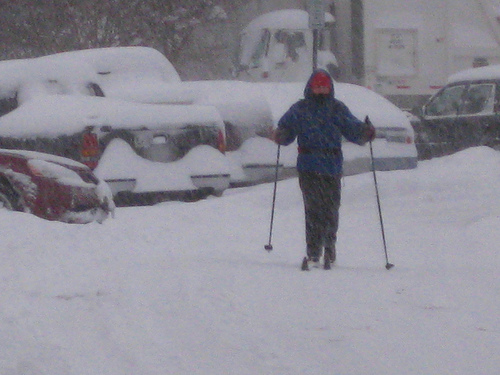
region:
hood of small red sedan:
[1, 145, 121, 226]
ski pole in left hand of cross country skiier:
[360, 111, 402, 274]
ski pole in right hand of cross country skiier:
[262, 118, 283, 257]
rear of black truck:
[3, 59, 233, 211]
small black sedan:
[408, 65, 498, 150]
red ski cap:
[307, 69, 337, 91]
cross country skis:
[294, 247, 339, 274]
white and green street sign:
[305, 1, 327, 75]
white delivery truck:
[237, 0, 499, 104]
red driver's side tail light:
[75, 128, 102, 170]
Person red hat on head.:
[306, 63, 333, 90]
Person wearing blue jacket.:
[295, 110, 347, 155]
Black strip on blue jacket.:
[292, 138, 348, 158]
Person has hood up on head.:
[296, 60, 339, 101]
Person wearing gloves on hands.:
[259, 110, 401, 141]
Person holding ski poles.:
[247, 102, 392, 169]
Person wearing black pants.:
[294, 189, 352, 242]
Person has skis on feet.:
[296, 243, 358, 270]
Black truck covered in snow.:
[102, 118, 202, 149]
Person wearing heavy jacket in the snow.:
[265, 61, 393, 278]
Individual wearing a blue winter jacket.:
[259, 67, 399, 274]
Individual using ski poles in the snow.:
[261, 68, 396, 273]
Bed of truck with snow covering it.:
[76, 104, 231, 205]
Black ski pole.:
[366, 124, 394, 277]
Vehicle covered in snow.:
[409, 67, 498, 155]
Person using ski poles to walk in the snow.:
[264, 60, 392, 274]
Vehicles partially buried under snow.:
[4, 49, 236, 224]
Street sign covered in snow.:
[309, 4, 328, 29]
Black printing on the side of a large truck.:
[381, 34, 408, 54]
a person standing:
[266, 73, 393, 285]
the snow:
[150, 301, 232, 374]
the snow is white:
[128, 274, 208, 344]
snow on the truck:
[103, 147, 195, 182]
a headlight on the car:
[29, 158, 82, 183]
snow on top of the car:
[455, 67, 495, 84]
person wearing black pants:
[300, 176, 336, 253]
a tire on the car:
[3, 185, 25, 214]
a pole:
[360, 139, 402, 276]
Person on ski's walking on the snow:
[259, 68, 394, 275]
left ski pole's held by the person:
[260, 129, 285, 257]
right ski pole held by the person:
[363, 116, 393, 271]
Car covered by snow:
[0, 66, 231, 198]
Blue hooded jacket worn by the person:
[277, 69, 368, 176]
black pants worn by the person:
[296, 169, 345, 264]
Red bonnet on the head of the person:
[308, 72, 334, 88]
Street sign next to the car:
[305, 0, 326, 68]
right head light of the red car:
[28, 156, 80, 185]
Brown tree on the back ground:
[2, 0, 238, 70]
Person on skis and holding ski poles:
[261, 66, 397, 272]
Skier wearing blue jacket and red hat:
[255, 66, 377, 262]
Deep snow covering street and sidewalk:
[1, 145, 499, 374]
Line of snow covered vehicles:
[1, 44, 498, 224]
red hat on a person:
[308, 68, 333, 89]